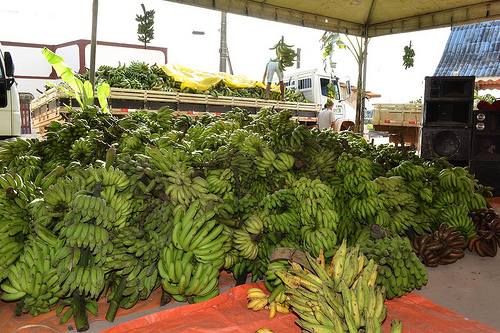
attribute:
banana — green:
[175, 271, 189, 300]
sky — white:
[1, 3, 445, 101]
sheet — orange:
[92, 276, 499, 333]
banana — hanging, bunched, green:
[133, 3, 160, 54]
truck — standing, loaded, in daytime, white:
[22, 66, 366, 143]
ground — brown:
[408, 247, 499, 324]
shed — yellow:
[338, 80, 384, 111]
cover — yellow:
[161, 58, 285, 98]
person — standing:
[314, 98, 340, 135]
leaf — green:
[41, 44, 88, 104]